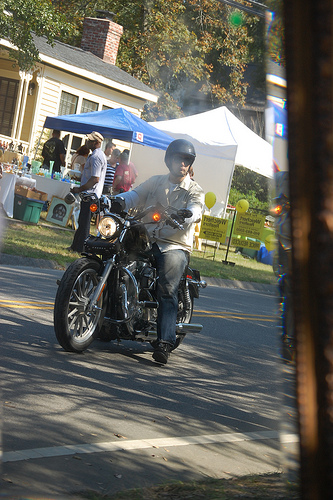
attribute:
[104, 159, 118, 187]
shirt — dark short sleeve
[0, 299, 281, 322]
line —  yellow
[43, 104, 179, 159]
tent — blue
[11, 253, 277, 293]
road —  side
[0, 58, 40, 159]
porch — open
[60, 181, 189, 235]
handlebars — handle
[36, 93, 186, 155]
top — blue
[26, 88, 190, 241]
tent — blue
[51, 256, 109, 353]
wheel —  front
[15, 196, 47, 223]
bucket — green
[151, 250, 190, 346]
jeans —  blue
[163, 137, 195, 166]
helmet — black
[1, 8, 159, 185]
home —  yellow 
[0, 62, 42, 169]
trim —  yellow 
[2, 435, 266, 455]
line — white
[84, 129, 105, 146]
hat — light colored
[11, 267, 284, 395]
street — asphalt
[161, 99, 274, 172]
canopy — white canopy style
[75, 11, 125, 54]
chimney — brick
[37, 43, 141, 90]
roof — top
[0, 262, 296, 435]
road — side 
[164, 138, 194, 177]
helmet — black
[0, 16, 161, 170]
house —  yellow 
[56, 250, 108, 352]
tire —  front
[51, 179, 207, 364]
motorcycle — black